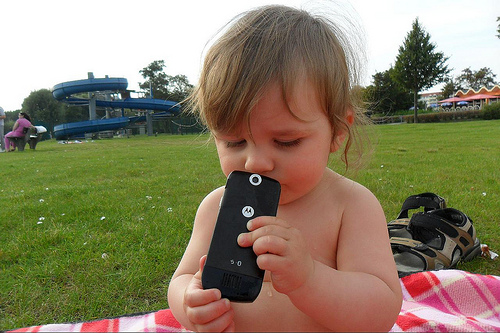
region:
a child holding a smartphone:
[128, 10, 410, 331]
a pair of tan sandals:
[388, 183, 483, 285]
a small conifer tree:
[386, 13, 449, 123]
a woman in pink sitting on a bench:
[1, 105, 46, 155]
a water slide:
[46, 60, 186, 151]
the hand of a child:
[239, 211, 311, 293]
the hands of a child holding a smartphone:
[177, 171, 293, 331]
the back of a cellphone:
[202, 168, 283, 304]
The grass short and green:
[13, 150, 163, 305]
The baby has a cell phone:
[144, 0, 428, 331]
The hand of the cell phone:
[237, 210, 316, 300]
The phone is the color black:
[198, 159, 278, 309]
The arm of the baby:
[301, 198, 408, 327]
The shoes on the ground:
[387, 173, 485, 288]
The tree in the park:
[388, 14, 443, 126]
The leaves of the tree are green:
[398, 37, 439, 82]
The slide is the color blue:
[41, 61, 188, 145]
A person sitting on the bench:
[1, 106, 47, 156]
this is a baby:
[142, 10, 445, 327]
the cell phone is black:
[194, 127, 303, 298]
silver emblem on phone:
[226, 190, 259, 227]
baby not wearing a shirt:
[156, 22, 419, 330]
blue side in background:
[20, 54, 176, 148]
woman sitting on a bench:
[3, 92, 40, 150]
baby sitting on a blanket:
[71, 0, 493, 328]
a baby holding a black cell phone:
[165, 3, 403, 330]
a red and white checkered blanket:
[1, 267, 498, 332]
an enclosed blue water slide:
[47, 68, 182, 141]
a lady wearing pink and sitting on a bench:
[3, 108, 44, 153]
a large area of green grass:
[0, 119, 498, 329]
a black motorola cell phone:
[200, 170, 279, 302]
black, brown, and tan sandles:
[382, 193, 479, 270]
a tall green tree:
[390, 15, 450, 122]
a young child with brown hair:
[165, 4, 401, 331]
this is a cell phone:
[192, 147, 295, 312]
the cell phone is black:
[197, 148, 288, 322]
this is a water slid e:
[31, 61, 199, 149]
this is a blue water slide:
[32, 56, 197, 159]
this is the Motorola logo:
[236, 205, 257, 224]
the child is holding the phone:
[144, 3, 428, 331]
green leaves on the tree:
[401, 48, 413, 61]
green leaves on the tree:
[366, 87, 383, 110]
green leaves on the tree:
[386, 82, 411, 107]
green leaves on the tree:
[424, 48, 441, 76]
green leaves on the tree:
[446, 61, 488, 86]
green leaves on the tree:
[163, 68, 188, 93]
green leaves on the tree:
[152, 80, 190, 105]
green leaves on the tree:
[20, 78, 55, 133]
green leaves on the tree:
[137, 63, 159, 78]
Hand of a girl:
[236, 216, 308, 291]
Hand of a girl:
[236, 210, 310, 299]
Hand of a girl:
[236, 213, 318, 299]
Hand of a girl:
[238, 210, 311, 292]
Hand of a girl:
[236, 208, 316, 295]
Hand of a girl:
[229, 214, 309, 287]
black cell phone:
[196, 166, 284, 303]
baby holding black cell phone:
[162, 0, 414, 330]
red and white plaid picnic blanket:
[0, 263, 499, 331]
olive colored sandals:
[380, 180, 487, 282]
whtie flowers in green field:
[28, 210, 52, 229]